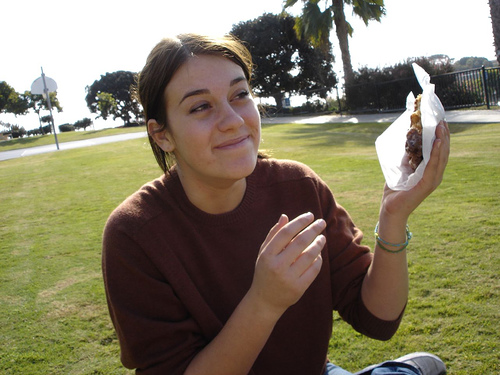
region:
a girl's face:
[154, 58, 264, 192]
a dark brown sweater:
[93, 150, 405, 371]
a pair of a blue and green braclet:
[370, 222, 417, 254]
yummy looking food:
[370, 73, 452, 185]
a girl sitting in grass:
[93, 25, 455, 372]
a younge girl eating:
[96, 29, 453, 374]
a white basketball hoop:
[26, 72, 71, 147]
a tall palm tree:
[278, 0, 389, 105]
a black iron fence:
[318, 65, 493, 109]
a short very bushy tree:
[227, 13, 338, 115]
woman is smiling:
[97, 28, 272, 193]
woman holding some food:
[340, 72, 497, 233]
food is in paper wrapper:
[341, 79, 481, 214]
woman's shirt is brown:
[65, 162, 482, 362]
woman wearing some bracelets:
[355, 214, 438, 275]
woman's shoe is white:
[336, 336, 461, 373]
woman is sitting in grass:
[1, 1, 448, 373]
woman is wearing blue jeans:
[314, 347, 406, 373]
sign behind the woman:
[16, 66, 144, 176]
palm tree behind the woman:
[298, 3, 409, 108]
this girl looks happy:
[91, 12, 331, 258]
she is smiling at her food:
[98, 32, 460, 212]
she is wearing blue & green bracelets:
[368, 213, 418, 288]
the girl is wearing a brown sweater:
[63, 164, 389, 366]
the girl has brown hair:
[135, 20, 281, 167]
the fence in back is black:
[343, 63, 498, 116]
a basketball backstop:
[13, 64, 75, 161]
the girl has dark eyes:
[178, 86, 261, 123]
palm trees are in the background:
[273, 1, 398, 53]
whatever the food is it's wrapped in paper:
[381, 56, 481, 218]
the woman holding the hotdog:
[96, 34, 485, 373]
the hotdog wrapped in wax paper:
[356, 53, 459, 206]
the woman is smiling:
[90, 20, 499, 325]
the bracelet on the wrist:
[371, 214, 418, 263]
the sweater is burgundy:
[93, 165, 399, 373]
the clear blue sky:
[80, 18, 122, 55]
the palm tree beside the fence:
[272, 0, 390, 112]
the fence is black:
[327, 74, 497, 109]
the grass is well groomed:
[20, 172, 93, 290]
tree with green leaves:
[238, 21, 332, 113]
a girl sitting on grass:
[97, 30, 452, 374]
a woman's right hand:
[252, 210, 322, 309]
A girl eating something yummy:
[97, 25, 452, 374]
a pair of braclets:
[371, 228, 411, 253]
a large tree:
[80, 74, 151, 125]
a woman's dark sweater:
[86, 177, 388, 372]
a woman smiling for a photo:
[118, 67, 348, 374]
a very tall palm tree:
[283, 0, 392, 107]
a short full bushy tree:
[223, 13, 338, 118]